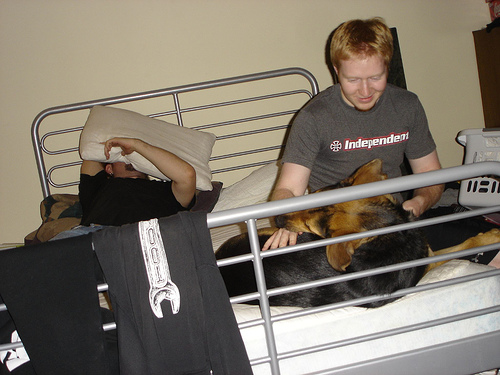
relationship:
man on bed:
[318, 34, 420, 145] [229, 179, 294, 292]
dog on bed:
[337, 187, 388, 256] [229, 179, 294, 292]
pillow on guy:
[84, 111, 187, 144] [87, 158, 150, 215]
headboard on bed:
[208, 87, 255, 128] [229, 179, 294, 292]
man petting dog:
[318, 34, 420, 145] [337, 187, 388, 256]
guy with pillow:
[87, 158, 150, 215] [84, 111, 187, 144]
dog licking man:
[337, 187, 388, 256] [318, 34, 420, 145]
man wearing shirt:
[318, 34, 420, 145] [329, 97, 389, 156]